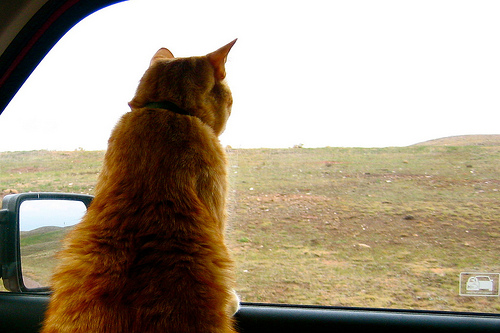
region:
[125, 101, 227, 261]
This is a cat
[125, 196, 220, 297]
The cat is large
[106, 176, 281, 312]
The cat is orange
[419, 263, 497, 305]
This is a picture of a sticker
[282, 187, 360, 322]
This is a window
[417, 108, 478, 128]
This is a hill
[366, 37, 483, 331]
The sky is white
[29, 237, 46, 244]
This is a car mirror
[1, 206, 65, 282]
The mirror is glass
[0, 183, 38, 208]
The outline is black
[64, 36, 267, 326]
the cat is brown in colour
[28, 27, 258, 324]
the cat is looking out of the window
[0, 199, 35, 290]
the side mirror is black in colour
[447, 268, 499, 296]
the window has a sticker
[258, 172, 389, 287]
the grass is small in size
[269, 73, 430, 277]
the window is closed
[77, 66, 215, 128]
the cat has a collar on the neck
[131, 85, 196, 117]
the collar is black on the neck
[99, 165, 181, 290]
the fur is large in size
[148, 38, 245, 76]
its ears are raised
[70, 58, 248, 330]
this is a cat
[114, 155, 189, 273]
the cat is brown in color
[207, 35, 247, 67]
this is an ear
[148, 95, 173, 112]
this is a ribbon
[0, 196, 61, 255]
this is aside mirror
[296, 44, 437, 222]
this is a window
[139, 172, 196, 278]
the cat is fury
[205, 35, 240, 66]
the ear is sharp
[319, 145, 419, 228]
the ground is dry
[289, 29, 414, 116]
the sky is white in collor